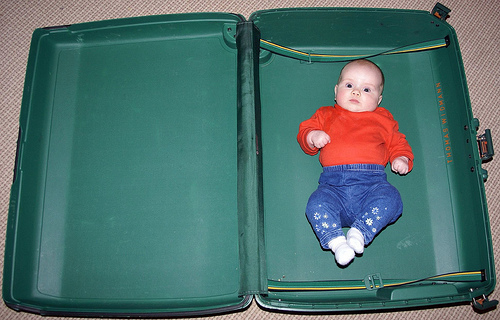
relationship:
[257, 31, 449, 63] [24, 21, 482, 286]
strap fastened on suitcase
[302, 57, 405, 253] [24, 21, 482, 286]
baby laying inside of suitcase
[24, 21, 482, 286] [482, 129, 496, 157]
suitcase has handle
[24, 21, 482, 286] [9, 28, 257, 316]
suitcase has top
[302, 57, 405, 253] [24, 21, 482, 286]
infant lying inside suitcase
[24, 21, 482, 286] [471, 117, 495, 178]
suitcase has lock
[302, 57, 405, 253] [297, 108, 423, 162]
baby wearing shirt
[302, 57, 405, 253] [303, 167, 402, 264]
baby dressed in jeans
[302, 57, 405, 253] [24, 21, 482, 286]
baby laying in suitcase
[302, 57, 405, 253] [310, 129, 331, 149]
baby clenching hand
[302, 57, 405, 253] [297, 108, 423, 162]
baby dressed in shirt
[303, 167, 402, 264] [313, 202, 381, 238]
jeans have pattern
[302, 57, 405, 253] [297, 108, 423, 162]
baby in shirt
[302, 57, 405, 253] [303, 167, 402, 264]
baby in jeans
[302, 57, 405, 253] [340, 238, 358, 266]
baby in socks